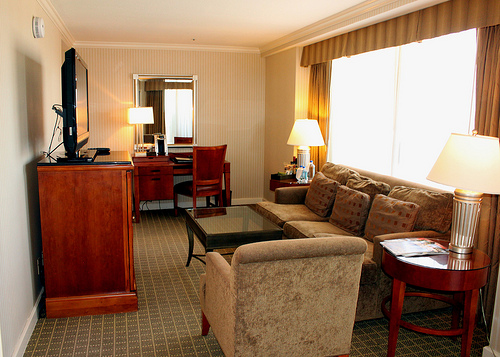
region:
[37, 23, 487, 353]
this is a hotel room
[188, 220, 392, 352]
a tan side chair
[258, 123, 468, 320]
this is a sofa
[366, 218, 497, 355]
a brown side table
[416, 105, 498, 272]
a table lamp on side of sofa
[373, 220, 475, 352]
this is a side table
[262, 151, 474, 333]
this is a couch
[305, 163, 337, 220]
this is a pilllow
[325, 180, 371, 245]
this is a pilllow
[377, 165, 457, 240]
this is a pilllow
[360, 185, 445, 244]
this is a pilllow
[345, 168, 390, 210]
this is a pilllow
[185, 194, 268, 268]
this is a table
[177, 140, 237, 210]
this is a chair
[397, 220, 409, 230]
a brown dot on a pillow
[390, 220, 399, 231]
a brown dot on a pillow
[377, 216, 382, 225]
a brown dot on a pillow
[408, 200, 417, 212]
a brown dot on a pillow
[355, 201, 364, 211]
a brown dot on a pillow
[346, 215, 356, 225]
a brown dot on a pillow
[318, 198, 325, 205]
a brown dot on a pillow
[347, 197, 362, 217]
a brown dot on a pillow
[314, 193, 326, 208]
a brown dot on a pillow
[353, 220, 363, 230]
a brown dot on a pillow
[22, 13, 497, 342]
this is a hotel room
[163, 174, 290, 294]
a glass coffee table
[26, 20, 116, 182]
this is a tv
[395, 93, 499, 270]
this is a lamp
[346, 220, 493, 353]
this is a side table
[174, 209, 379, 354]
this is a brown chair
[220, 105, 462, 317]
this is a sofa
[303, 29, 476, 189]
window behind the sofa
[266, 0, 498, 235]
gold curtains on window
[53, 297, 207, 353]
carpet on the floor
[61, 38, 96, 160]
TV on a dresser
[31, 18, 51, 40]
smoke detector on a wall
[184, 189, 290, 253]
coffee table in front of a sofa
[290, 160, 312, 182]
bottle on a end table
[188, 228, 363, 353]
arm chair in front of a coffee table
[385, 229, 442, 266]
magazine on a table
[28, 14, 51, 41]
smoke detector on the wall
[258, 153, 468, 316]
this is a sofa set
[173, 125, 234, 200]
this is a chair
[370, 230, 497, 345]
this is a table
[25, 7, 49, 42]
a white smoke alarm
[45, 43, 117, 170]
a black flat screen tv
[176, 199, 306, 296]
a glass coffee table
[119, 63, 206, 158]
a silver framed mirror on the wall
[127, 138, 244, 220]
a wooden desk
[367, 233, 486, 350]
a small pile of magazines on an end table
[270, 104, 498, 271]
two table lamps on end tables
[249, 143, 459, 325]
a couch with several pillows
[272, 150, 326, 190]
small objects on an end table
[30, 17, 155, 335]
tv on top of console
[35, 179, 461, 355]
a plaid carpet floor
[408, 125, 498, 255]
lamp on a table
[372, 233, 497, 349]
the table is brown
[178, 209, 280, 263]
black trim on table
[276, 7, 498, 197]
a large window behind the sofa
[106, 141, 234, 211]
desk on the side of the room